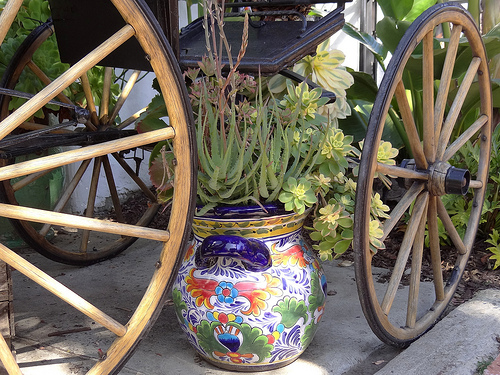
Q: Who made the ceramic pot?
A: Chinese people.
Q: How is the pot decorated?
A: With flowers.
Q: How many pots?
A: One.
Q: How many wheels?
A: Three.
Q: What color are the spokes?
A: Tan.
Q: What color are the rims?
A: Black.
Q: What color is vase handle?
A: Blue.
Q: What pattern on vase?
A: Floral.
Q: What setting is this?
A: Garden.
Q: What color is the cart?
A: Black.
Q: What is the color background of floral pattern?
A: White.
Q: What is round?
A: Wheels.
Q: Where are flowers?
A: In a pot.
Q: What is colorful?
A: Flower pot.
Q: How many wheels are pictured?
A: Three.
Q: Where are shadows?
A: On the ground.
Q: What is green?
A: Plants.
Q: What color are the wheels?
A: Brown and black.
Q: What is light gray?
A: Pavement.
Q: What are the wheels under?
A: An antique buggy.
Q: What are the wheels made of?
A: Wood.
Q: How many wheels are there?
A: Three.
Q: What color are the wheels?
A: Brown and black.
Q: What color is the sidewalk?
A: Gray.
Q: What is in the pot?
A: Plants.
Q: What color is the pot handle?
A: Blue.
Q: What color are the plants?
A: Green.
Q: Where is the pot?
A: On the sidewalk.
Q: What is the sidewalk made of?
A: Cement.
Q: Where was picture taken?
A: Garden.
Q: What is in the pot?
A: Plant.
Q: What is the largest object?
A: Wagon wheels.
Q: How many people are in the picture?
A: None.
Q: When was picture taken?
A: Daytime.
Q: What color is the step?
A: Black.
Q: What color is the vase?
A: Multi colored.